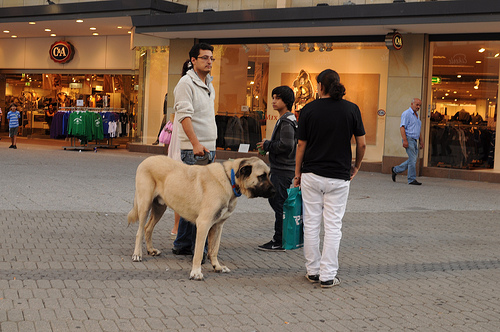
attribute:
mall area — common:
[4, 146, 497, 328]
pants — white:
[285, 169, 367, 285]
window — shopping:
[218, 44, 278, 166]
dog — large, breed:
[126, 153, 276, 280]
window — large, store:
[419, 31, 499, 181]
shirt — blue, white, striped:
[6, 112, 22, 127]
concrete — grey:
[4, 133, 498, 210]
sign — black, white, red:
[47, 39, 74, 64]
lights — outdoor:
[189, 37, 387, 51]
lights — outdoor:
[0, 22, 134, 43]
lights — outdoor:
[472, 44, 498, 69]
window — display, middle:
[217, 47, 267, 119]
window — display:
[431, 39, 498, 167]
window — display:
[69, 71, 131, 128]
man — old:
[388, 93, 425, 188]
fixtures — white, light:
[7, 12, 129, 52]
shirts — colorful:
[66, 106, 136, 138]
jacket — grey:
[264, 112, 302, 169]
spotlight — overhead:
[241, 43, 252, 53]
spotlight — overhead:
[325, 41, 332, 51]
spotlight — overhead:
[315, 40, 324, 52]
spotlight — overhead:
[306, 41, 316, 53]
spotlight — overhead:
[294, 41, 306, 53]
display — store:
[280, 59, 317, 122]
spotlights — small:
[238, 38, 333, 55]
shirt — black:
[292, 93, 366, 183]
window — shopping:
[210, 39, 386, 166]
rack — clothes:
[213, 110, 265, 151]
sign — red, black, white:
[382, 26, 404, 52]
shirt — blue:
[397, 109, 427, 141]